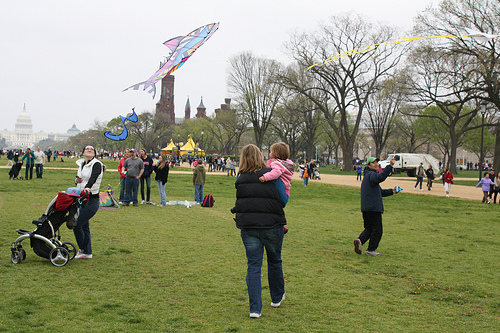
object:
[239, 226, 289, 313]
jeans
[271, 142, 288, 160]
hair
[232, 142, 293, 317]
woman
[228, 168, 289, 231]
vest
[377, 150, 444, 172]
truck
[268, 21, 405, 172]
bare tree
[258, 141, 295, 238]
baby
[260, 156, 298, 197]
jacket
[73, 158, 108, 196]
white vest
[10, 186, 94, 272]
black stroller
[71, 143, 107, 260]
lady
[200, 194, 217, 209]
backpack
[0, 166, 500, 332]
grass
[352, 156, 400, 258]
man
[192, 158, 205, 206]
people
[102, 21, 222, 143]
kites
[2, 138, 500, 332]
park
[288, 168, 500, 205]
walkway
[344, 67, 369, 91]
branches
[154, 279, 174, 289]
small patch